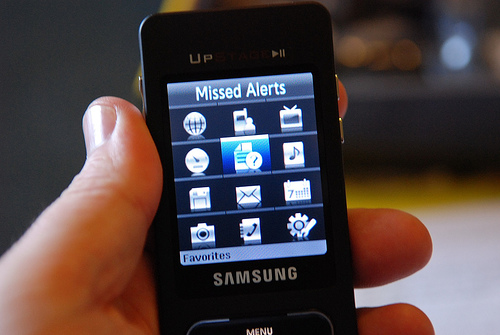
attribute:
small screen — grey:
[162, 74, 347, 266]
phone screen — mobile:
[170, 76, 350, 286]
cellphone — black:
[137, 1, 356, 332]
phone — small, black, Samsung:
[135, 3, 363, 333]